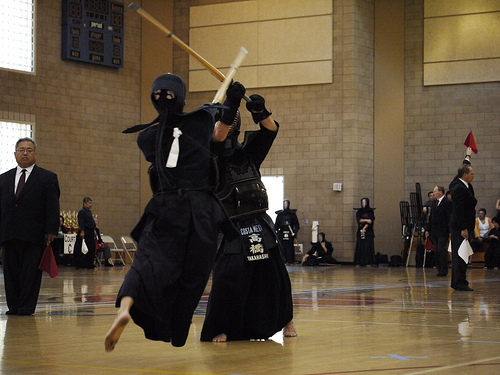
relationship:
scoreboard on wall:
[54, 0, 129, 72] [2, 0, 147, 245]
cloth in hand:
[463, 130, 478, 155] [462, 146, 472, 158]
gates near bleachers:
[401, 175, 427, 222] [408, 230, 446, 262]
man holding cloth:
[449, 145, 478, 291] [457, 233, 474, 267]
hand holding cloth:
[464, 140, 480, 163] [456, 126, 486, 161]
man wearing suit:
[0, 135, 60, 317] [0, 167, 60, 311]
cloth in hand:
[39, 239, 72, 283] [462, 144, 476, 165]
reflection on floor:
[442, 291, 496, 345] [417, 310, 499, 371]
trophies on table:
[59, 204, 84, 231] [63, 227, 75, 247]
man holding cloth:
[449, 145, 478, 291] [463, 130, 478, 155]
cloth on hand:
[463, 130, 478, 155] [459, 139, 475, 164]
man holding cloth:
[449, 145, 478, 291] [458, 238, 474, 265]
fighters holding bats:
[104, 72, 298, 352] [126, 0, 251, 103]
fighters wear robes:
[85, 51, 328, 316] [91, 125, 280, 292]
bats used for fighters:
[126, 3, 247, 105] [104, 72, 298, 352]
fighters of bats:
[104, 72, 298, 352] [126, 3, 247, 105]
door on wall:
[264, 176, 283, 225] [169, 2, 371, 254]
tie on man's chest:
[16, 168, 39, 195] [1, 167, 42, 229]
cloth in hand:
[458, 238, 474, 265] [466, 146, 473, 156]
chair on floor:
[116, 233, 141, 266] [10, 261, 492, 371]